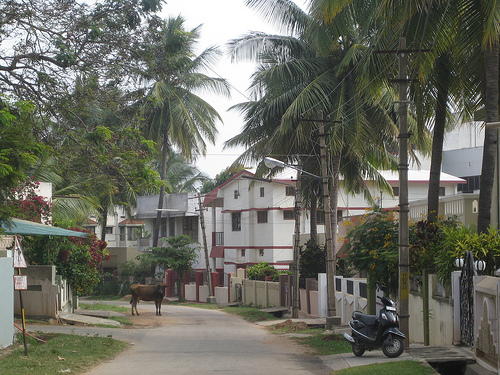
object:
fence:
[318, 270, 500, 367]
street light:
[155, 208, 178, 211]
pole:
[292, 161, 303, 318]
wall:
[31, 292, 51, 315]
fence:
[165, 269, 320, 318]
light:
[474, 260, 486, 274]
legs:
[155, 300, 160, 313]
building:
[432, 111, 500, 193]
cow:
[129, 283, 167, 316]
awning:
[1, 216, 91, 238]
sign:
[14, 276, 28, 291]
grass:
[220, 306, 276, 322]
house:
[0, 181, 90, 348]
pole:
[17, 268, 27, 355]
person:
[15, 241, 21, 265]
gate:
[459, 251, 475, 351]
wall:
[242, 275, 499, 360]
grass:
[296, 332, 353, 355]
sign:
[13, 232, 27, 268]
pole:
[197, 193, 213, 296]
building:
[163, 168, 467, 306]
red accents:
[214, 246, 222, 256]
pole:
[318, 109, 338, 316]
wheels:
[352, 339, 365, 356]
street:
[13, 322, 128, 344]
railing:
[214, 232, 224, 246]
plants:
[338, 209, 498, 297]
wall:
[273, 223, 293, 244]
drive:
[135, 322, 264, 370]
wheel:
[382, 336, 404, 358]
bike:
[344, 296, 406, 358]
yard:
[187, 263, 369, 298]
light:
[264, 157, 284, 169]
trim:
[221, 207, 295, 213]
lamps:
[455, 258, 464, 268]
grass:
[0, 331, 121, 375]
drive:
[254, 317, 328, 329]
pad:
[322, 345, 476, 371]